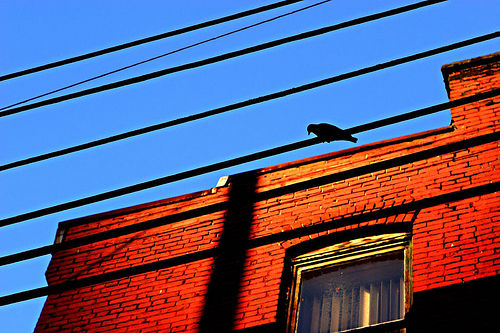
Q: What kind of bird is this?
A: A crow.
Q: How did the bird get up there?
A: It flew.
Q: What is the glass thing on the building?
A: A window.